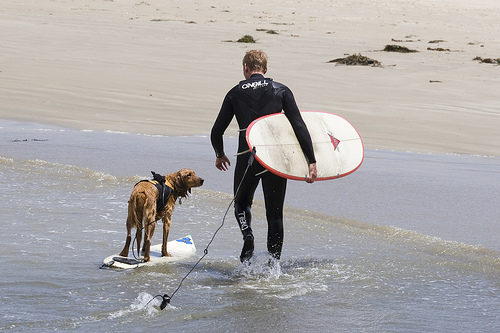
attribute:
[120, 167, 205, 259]
dog — brown, wearing, wet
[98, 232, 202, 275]
surfboard — white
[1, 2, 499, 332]
sand — brown, tan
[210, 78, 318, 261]
suit — black, wet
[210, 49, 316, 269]
man — standing, holding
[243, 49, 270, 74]
hair — blonde, brown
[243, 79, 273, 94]
symbol — white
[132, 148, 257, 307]
cable — attached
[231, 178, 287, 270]
leg — up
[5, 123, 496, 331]
water — clear, shallow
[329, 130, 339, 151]
logo — red